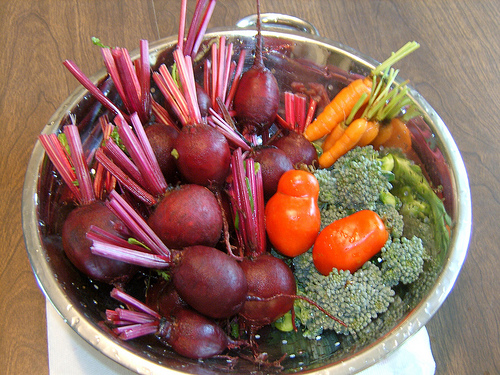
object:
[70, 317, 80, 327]
water droplets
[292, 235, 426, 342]
broccoli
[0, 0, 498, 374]
table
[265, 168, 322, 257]
cherry tomato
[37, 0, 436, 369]
vegetable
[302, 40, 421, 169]
carrots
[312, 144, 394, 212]
broccoli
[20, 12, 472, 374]
bowl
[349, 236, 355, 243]
water drops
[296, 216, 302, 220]
water drops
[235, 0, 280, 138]
radishes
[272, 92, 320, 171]
radishes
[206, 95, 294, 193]
radishes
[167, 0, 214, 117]
radishes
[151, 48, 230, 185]
radishes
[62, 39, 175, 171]
radishes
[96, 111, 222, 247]
radishes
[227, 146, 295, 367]
radishes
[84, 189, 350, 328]
radishes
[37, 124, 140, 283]
radishes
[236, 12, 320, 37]
handle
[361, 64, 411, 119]
carrot stems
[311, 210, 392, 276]
orange peppers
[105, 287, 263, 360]
radishes